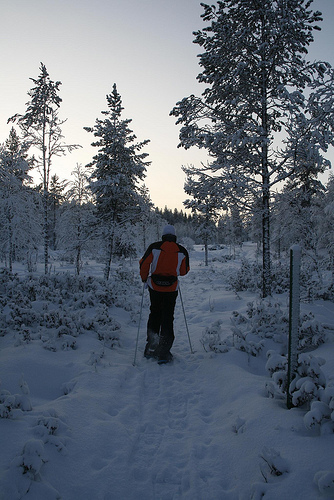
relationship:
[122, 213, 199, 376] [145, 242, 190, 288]
skier with jacket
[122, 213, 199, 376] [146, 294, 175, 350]
skier wearing pants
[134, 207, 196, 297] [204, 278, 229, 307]
person walking in snow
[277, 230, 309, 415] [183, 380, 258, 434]
post on right of trail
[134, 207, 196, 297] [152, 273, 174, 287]
person wearing fanny pack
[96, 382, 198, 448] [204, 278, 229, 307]
path through snow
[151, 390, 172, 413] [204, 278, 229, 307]
footprint in snow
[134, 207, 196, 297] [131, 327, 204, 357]
person has two poles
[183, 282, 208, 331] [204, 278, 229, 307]
tracks in snow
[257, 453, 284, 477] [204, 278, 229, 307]
grass poking up through snow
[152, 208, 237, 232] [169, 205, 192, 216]
pine trees in distance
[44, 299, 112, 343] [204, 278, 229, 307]
brush covered in snow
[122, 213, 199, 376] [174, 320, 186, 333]
skier going uphill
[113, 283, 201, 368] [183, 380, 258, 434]
skiing on a trail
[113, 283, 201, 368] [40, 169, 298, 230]
skiing in forest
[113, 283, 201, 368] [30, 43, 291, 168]
skiing among trees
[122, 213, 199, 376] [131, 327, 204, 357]
skier has poles